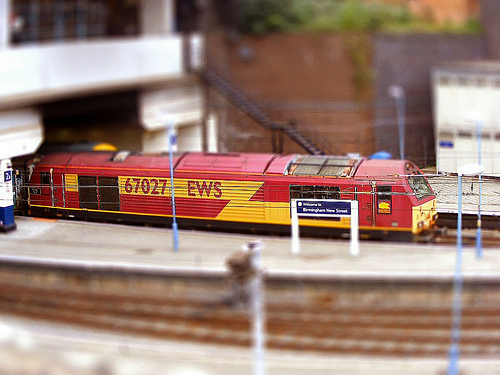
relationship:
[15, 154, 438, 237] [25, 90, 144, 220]
toy train coming out of tunnel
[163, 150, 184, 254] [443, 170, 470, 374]
pole on pole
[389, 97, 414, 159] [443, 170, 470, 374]
pole on pole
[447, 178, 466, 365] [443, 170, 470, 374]
blue paint on pole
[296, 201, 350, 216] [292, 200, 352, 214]
sign on a blue background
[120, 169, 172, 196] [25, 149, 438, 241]
numbers on side of train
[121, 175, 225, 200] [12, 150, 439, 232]
red writing on side of train